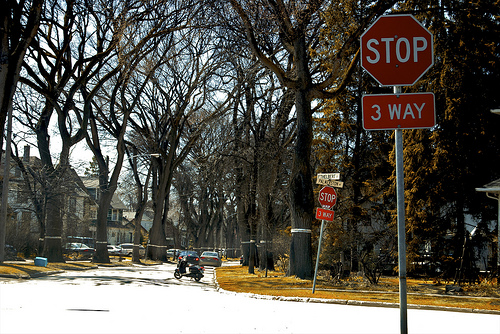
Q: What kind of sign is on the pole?
A: A stop sign.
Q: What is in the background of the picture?
A: Trees.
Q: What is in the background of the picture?
A: Houses.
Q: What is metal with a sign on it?
A: A pole.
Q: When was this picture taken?
A: On a clear sunny day.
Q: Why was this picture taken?
A: To display the street.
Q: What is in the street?
A: A motorcycle.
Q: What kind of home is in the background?
A: A large home.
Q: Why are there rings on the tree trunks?
A: They are marked to be cut.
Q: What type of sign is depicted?
A: A 3-way STOP sign.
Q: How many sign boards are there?
A: 2.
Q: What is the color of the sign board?
A: Red and white.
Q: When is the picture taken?
A: Daytime.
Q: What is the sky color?
A: Blue.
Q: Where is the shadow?
A: In the road.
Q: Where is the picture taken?
A: At a intersection.